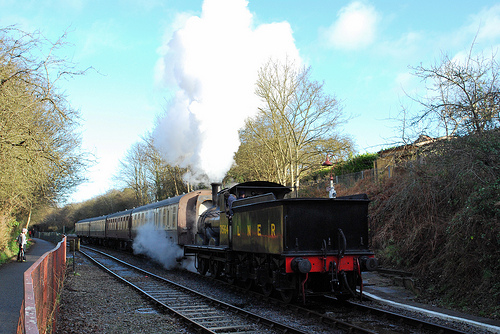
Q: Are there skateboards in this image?
A: No, there are no skateboards.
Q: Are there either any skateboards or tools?
A: No, there are no skateboards or tools.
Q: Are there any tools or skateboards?
A: No, there are no skateboards or tools.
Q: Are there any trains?
A: Yes, there is a train.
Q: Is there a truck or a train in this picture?
A: Yes, there is a train.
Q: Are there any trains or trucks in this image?
A: Yes, there is a train.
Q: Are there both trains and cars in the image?
A: Yes, there are both a train and a car.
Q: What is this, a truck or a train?
A: This is a train.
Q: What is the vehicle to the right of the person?
A: The vehicle is a train.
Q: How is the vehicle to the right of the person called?
A: The vehicle is a train.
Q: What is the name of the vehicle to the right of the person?
A: The vehicle is a train.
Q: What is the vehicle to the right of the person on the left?
A: The vehicle is a train.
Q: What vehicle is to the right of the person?
A: The vehicle is a train.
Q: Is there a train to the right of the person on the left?
A: Yes, there is a train to the right of the person.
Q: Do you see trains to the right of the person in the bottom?
A: Yes, there is a train to the right of the person.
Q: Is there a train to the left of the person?
A: No, the train is to the right of the person.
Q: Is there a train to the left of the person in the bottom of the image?
A: No, the train is to the right of the person.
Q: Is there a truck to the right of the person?
A: No, there is a train to the right of the person.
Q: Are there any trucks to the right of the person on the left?
A: No, there is a train to the right of the person.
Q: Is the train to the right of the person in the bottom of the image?
A: Yes, the train is to the right of the person.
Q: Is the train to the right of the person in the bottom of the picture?
A: Yes, the train is to the right of the person.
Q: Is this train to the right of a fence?
A: No, the train is to the right of the person.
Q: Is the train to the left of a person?
A: No, the train is to the right of a person.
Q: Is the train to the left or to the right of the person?
A: The train is to the right of the person.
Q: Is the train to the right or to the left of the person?
A: The train is to the right of the person.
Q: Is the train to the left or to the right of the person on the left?
A: The train is to the right of the person.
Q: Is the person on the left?
A: Yes, the person is on the left of the image.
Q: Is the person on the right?
A: No, the person is on the left of the image.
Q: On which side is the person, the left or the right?
A: The person is on the left of the image.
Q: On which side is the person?
A: The person is on the left of the image.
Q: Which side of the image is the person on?
A: The person is on the left of the image.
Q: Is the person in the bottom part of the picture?
A: Yes, the person is in the bottom of the image.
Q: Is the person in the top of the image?
A: No, the person is in the bottom of the image.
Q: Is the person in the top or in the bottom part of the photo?
A: The person is in the bottom of the image.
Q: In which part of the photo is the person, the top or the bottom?
A: The person is in the bottom of the image.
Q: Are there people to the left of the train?
A: Yes, there is a person to the left of the train.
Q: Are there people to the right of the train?
A: No, the person is to the left of the train.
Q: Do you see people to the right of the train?
A: No, the person is to the left of the train.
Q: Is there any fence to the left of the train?
A: No, there is a person to the left of the train.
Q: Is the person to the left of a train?
A: Yes, the person is to the left of a train.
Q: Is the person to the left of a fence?
A: No, the person is to the left of a train.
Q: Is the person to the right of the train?
A: No, the person is to the left of the train.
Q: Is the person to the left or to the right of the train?
A: The person is to the left of the train.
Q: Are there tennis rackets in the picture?
A: No, there are no tennis rackets.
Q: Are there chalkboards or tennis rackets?
A: No, there are no tennis rackets or chalkboards.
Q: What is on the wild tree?
A: The leaves are on the tree.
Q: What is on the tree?
A: The leaves are on the tree.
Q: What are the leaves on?
A: The leaves are on the tree.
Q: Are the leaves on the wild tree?
A: Yes, the leaves are on the tree.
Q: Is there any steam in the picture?
A: Yes, there is steam.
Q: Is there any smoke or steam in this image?
A: Yes, there is steam.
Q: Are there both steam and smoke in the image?
A: Yes, there are both steam and smoke.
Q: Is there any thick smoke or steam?
A: Yes, there is thick steam.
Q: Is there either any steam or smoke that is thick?
A: Yes, the steam is thick.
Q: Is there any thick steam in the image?
A: Yes, there is thick steam.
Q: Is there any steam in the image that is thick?
A: Yes, there is steam that is thick.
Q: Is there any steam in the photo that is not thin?
A: Yes, there is thick steam.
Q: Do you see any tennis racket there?
A: No, there are no rackets.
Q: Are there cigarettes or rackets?
A: No, there are no rackets or cigarettes.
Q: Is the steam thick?
A: Yes, the steam is thick.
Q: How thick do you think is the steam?
A: The steam is thick.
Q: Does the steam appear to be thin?
A: No, the steam is thick.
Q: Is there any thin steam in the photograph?
A: No, there is steam but it is thick.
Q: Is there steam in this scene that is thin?
A: No, there is steam but it is thick.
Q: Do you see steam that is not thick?
A: No, there is steam but it is thick.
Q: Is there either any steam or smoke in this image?
A: Yes, there is smoke.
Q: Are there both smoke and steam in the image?
A: Yes, there are both smoke and steam.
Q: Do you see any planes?
A: No, there are no planes.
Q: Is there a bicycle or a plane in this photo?
A: No, there are no airplanes or bicycles.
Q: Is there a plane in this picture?
A: No, there are no airplanes.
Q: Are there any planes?
A: No, there are no planes.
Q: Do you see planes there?
A: No, there are no planes.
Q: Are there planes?
A: No, there are no planes.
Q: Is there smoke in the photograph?
A: Yes, there is smoke.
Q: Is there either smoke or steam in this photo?
A: Yes, there is smoke.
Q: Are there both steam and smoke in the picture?
A: Yes, there are both smoke and steam.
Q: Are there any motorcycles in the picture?
A: No, there are no motorcycles.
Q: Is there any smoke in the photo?
A: Yes, there is smoke.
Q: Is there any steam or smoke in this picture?
A: Yes, there is smoke.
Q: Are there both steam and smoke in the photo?
A: Yes, there are both smoke and steam.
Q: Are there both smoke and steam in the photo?
A: Yes, there are both smoke and steam.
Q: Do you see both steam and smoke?
A: Yes, there are both smoke and steam.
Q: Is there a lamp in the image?
A: No, there are no lamps.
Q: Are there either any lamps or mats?
A: No, there are no lamps or mats.